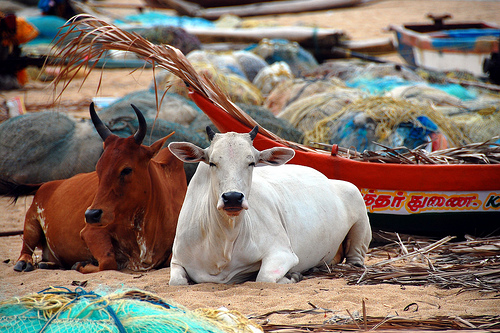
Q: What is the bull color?
A: Brown.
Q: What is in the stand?
A: Sticks.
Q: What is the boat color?
A: Red.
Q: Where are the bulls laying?
A: Sand.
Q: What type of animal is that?
A: Cow.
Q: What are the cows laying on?
A: Sand.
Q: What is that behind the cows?
A: A boat.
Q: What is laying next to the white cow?
A: Drift wood.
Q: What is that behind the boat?
A: Fishing nets.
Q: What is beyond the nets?
A: Boats.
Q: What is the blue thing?
A: Buoy.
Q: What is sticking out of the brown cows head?
A: Horns.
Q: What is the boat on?
A: Sand.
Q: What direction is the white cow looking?
A: Directly ahead.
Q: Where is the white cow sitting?
A: On the ground.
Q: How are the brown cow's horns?
A: Long.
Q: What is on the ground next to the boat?
A: Pile of sticks.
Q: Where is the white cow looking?
A: At the camera.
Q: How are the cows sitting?
A: Close.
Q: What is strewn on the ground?
A: Garbage.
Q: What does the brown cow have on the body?
A: White spots.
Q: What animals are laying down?
A: Cows.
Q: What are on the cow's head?
A: Horns.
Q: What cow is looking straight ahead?
A: White cow.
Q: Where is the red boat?
A: Behind the cows.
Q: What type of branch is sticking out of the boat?
A: A palm.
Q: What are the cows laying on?
A: Sand.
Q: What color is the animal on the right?
A: White.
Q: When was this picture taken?
A: Daytime.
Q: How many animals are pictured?
A: 2.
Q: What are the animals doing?
A: Laying down.